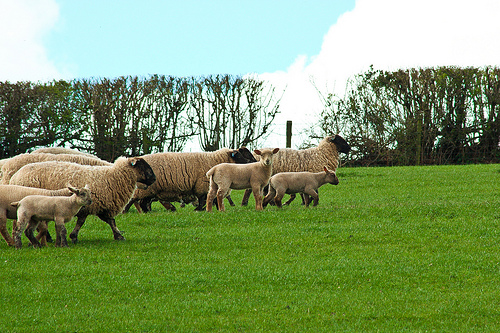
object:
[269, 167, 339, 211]
sheep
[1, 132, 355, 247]
herd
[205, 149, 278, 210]
sheep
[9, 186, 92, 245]
sheep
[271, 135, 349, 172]
sheep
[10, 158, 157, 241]
sheep